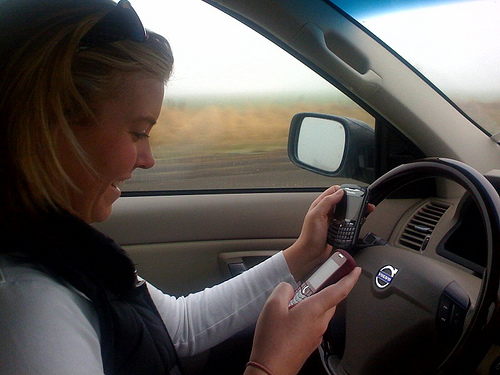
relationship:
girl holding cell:
[1, 0, 374, 374] [329, 181, 364, 250]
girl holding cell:
[1, 0, 374, 374] [292, 250, 347, 308]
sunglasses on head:
[76, 0, 150, 51] [1, 0, 176, 225]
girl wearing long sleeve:
[1, 0, 374, 374] [136, 249, 300, 358]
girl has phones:
[1, 0, 374, 374] [323, 180, 372, 248]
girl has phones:
[1, 0, 374, 374] [277, 250, 357, 300]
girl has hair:
[1, 0, 374, 374] [3, 2, 105, 182]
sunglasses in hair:
[76, 0, 150, 51] [5, 3, 171, 185]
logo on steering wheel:
[372, 264, 398, 290] [325, 159, 484, 373]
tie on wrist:
[240, 357, 278, 374] [239, 350, 308, 373]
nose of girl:
[134, 137, 156, 171] [1, 0, 374, 374]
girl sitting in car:
[1, 0, 374, 374] [7, 2, 499, 373]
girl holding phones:
[1, 0, 374, 374] [277, 175, 393, 295]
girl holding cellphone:
[1, 0, 374, 374] [331, 181, 366, 251]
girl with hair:
[1, 0, 374, 374] [4, 3, 151, 210]